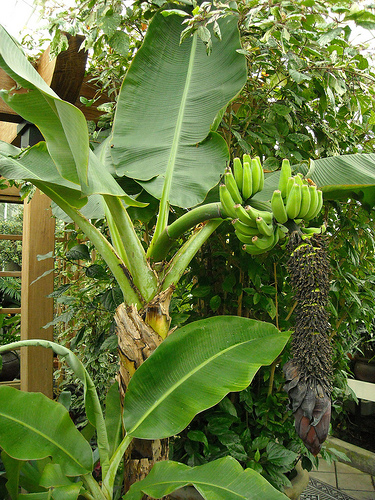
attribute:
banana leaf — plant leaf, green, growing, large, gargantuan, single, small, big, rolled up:
[119, 311, 297, 444]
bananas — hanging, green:
[207, 147, 342, 253]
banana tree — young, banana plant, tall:
[0, 21, 315, 497]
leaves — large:
[16, 0, 255, 211]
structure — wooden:
[0, 175, 73, 401]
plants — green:
[193, 376, 306, 478]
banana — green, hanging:
[267, 186, 291, 225]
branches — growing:
[66, 177, 213, 287]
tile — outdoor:
[312, 452, 373, 491]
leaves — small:
[161, 2, 231, 57]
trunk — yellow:
[107, 301, 180, 490]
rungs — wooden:
[3, 230, 26, 328]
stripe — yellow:
[123, 332, 259, 433]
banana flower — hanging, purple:
[280, 235, 346, 452]